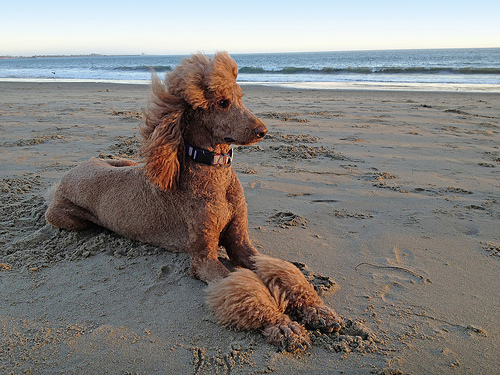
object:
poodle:
[44, 51, 340, 351]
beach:
[1, 83, 499, 374]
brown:
[123, 194, 190, 230]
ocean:
[0, 48, 499, 80]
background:
[0, 0, 499, 79]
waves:
[92, 62, 499, 74]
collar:
[184, 146, 234, 166]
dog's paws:
[263, 315, 311, 349]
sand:
[324, 331, 394, 359]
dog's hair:
[149, 67, 183, 108]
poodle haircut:
[124, 48, 240, 189]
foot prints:
[269, 209, 295, 227]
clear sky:
[0, 0, 499, 49]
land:
[0, 52, 149, 56]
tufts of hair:
[202, 266, 269, 328]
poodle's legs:
[190, 243, 310, 348]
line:
[0, 52, 499, 62]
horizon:
[0, 44, 497, 59]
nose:
[253, 127, 268, 138]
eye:
[217, 97, 231, 109]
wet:
[0, 77, 498, 96]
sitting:
[43, 158, 344, 352]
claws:
[296, 343, 304, 350]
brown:
[29, 260, 147, 340]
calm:
[0, 50, 499, 65]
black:
[259, 132, 264, 138]